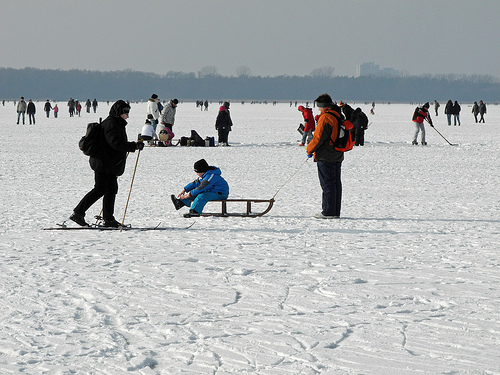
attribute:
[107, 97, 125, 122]
hair — black 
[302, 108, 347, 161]
jacket — orange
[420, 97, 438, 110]
hat — black 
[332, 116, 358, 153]
back pack — orange , black 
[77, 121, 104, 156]
back pack — black 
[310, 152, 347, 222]
pants — dark 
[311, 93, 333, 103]
hair — brown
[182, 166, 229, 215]
coat — blue 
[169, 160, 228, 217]
boy — little 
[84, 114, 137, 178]
jacket — black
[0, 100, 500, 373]
snow — white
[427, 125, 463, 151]
stick — wooden 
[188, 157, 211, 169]
hat — black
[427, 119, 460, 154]
stick — hockey